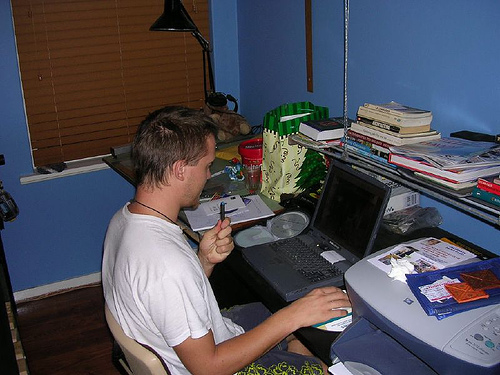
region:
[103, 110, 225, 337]
this is a man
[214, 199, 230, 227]
the hand is holding a pen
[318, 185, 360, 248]
this is a laptop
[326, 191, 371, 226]
the screen is off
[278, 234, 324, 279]
the keyboard is grey in color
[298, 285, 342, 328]
the hand is on the mouse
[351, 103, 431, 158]
the books are arranged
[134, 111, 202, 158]
the hair is short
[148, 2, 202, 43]
this is a lampstand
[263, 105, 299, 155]
the bag is green in color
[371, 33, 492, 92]
blue colored wall paint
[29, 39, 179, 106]
brown horizontal pull up blinds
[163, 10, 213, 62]
black metal reaching out desk lamp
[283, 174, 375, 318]
black laptop with no power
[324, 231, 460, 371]
gray and blue printer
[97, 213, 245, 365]
white t shirt on man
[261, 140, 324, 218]
yellow and brown gift bag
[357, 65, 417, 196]
a stack of books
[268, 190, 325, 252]
a CD next to the laptop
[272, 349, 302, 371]
gray and green shorts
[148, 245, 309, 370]
the arm of a man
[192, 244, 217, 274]
the arm of a man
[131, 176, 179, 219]
the neck of a man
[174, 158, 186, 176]
the ear of a man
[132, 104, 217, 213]
the head of a man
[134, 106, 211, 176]
the brown short hair of a man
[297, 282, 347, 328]
the hand of a man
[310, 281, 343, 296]
the finger of a man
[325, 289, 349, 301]
the finger of a man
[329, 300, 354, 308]
the finger of a man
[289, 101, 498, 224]
Book shelf with several books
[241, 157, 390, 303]
Grey and black computer laptop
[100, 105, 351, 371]
Young man sits at computer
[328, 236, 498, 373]
Grey and blue computer printer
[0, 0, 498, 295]
Sky blue painted walls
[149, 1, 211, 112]
Black desk lamp turned off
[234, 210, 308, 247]
CD in CD case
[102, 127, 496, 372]
desk with computer, printer, and various other objects.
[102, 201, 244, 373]
white shirt worn by young man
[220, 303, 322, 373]
Grey and lime green shorts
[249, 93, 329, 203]
Holiday gift bag with a Christmas tree on it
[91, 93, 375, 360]
Guy sitting at a desk using a laptop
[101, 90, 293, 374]
Guy is wearing a white t-shirt and grey shorts with yellow designs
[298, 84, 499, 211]
Stacks of books are on the shelf above the desk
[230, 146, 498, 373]
A printer and a laptop sitting on the desk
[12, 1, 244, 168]
Dark brown vertical miniblinds hang over the window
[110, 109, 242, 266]
Guy is holding something in his left hand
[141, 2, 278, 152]
Black desk lamp in the corner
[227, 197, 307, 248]
Opened CD case showing one CD and one empty sleeve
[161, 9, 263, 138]
Some kind of stuffed animal lying underneath the desk lamp